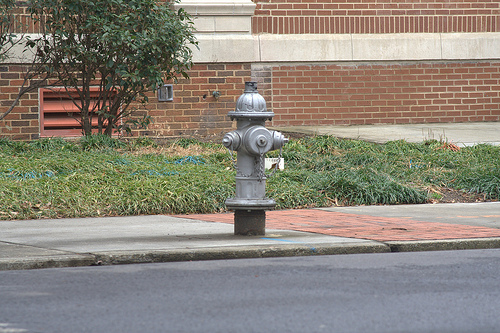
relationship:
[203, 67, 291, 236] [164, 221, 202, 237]
hydrant on sidewalk